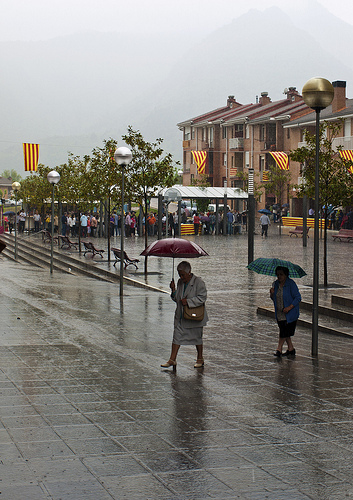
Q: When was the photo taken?
A: Daytime.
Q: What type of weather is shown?
A: Rainy.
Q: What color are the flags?
A: Yellow and red.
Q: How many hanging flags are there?
A: Four.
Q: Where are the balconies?
A: Building.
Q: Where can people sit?
A: Benches.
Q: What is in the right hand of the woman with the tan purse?
A: Umbrella.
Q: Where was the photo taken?
A: On the street, near the tracks.